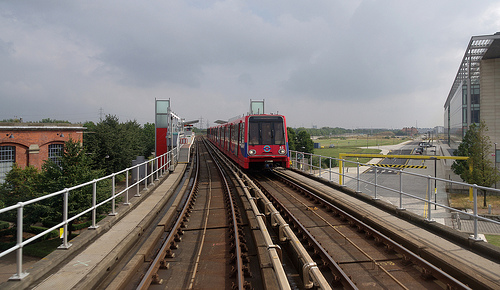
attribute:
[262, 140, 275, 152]
circle — neon blue, on train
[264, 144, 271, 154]
circle — on train, neon blue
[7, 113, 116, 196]
building — orange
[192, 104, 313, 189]
train — red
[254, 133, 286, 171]
spots — blue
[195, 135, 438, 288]
tracks — train tracks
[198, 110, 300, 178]
train — elevated, red, commuter train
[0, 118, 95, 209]
building — red, Brick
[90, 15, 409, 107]
clouds — grey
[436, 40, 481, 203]
building — tall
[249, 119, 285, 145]
windshield — large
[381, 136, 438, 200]
street — below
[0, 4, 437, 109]
clouds — dark gray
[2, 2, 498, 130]
skies — white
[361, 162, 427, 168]
post — yellow, black, overhead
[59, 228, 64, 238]
sign — small, yellow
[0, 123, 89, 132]
roof — white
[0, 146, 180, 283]
railing — large, silver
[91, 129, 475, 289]
train tracks — large, brown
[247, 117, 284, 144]
window — large, clear